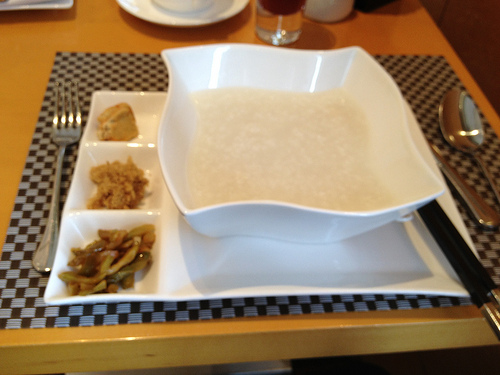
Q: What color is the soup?
A: White.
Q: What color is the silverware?
A: Silver.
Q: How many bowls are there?
A: One.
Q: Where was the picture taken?
A: The cafe.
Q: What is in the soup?
A: Rice.